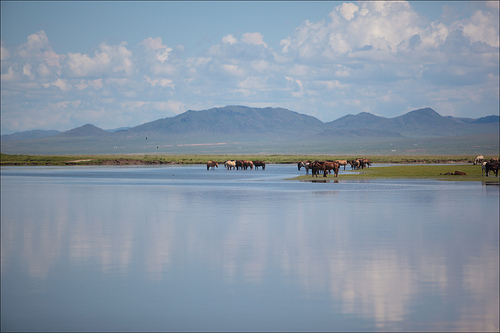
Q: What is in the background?
A: Mountains.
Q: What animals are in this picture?
A: Horses.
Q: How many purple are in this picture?
A: None.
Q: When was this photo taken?
A: Day time.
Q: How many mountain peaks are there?
A: Four.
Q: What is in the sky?
A: Clouds.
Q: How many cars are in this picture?
A: None.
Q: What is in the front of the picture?
A: Water.